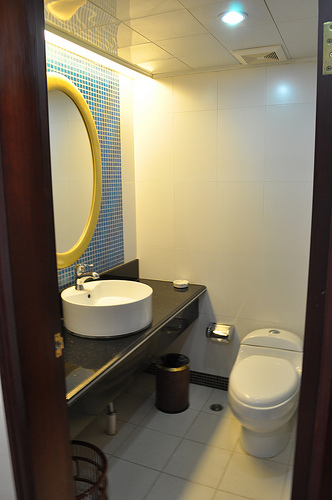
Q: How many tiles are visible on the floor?
A: 15 tiles.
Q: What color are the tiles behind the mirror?
A: The tiles are blue.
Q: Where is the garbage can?
A: Under the sink.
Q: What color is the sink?
A: White.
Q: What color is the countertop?
A: Black.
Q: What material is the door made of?
A: Wood.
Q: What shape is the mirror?
A: Circle.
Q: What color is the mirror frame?
A: Yellow.